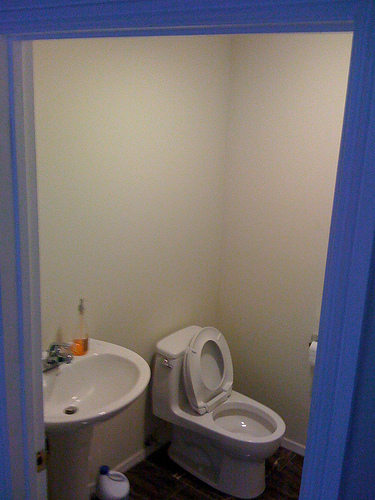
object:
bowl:
[211, 396, 277, 441]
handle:
[47, 334, 73, 358]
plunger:
[160, 365, 171, 372]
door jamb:
[33, 441, 48, 474]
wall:
[4, 0, 369, 497]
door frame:
[0, 2, 375, 500]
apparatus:
[156, 347, 175, 373]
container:
[71, 294, 89, 356]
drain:
[62, 403, 79, 414]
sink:
[38, 337, 151, 499]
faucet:
[39, 342, 73, 366]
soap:
[73, 333, 88, 354]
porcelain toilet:
[152, 322, 286, 500]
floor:
[282, 453, 307, 497]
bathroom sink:
[39, 335, 148, 498]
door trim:
[0, 4, 31, 85]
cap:
[97, 462, 110, 476]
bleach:
[91, 464, 132, 500]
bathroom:
[0, 0, 375, 500]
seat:
[187, 323, 235, 415]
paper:
[308, 340, 317, 370]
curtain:
[296, 8, 362, 498]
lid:
[181, 327, 235, 414]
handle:
[161, 359, 173, 370]